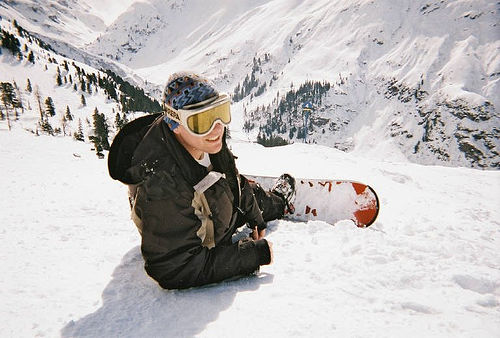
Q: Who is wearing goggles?
A: Snowboarder.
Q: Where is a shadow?
A: On the snow.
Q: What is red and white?
A: Snowboard.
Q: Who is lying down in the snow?
A: A snowboarder.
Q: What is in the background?
A: Trees.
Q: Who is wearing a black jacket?
A: A snowboarder.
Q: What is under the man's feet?
A: A snowboard.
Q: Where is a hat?
A: On man's head.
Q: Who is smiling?
A: The snowboarder.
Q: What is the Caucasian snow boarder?
A: Smiling.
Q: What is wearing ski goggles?
A: The man.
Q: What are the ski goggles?
A: Yellow.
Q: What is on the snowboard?
A: The man.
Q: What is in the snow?
A: Trees.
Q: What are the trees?
A: Pine.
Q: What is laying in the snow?
A: The man.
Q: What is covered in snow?
A: The mountains.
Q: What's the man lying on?
A: Snow.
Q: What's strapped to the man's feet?
A: Snowboard.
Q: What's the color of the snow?
A: White.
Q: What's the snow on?
A: Mountain.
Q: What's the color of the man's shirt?
A: White.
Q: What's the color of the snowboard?
A: Red and white.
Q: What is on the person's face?
A: Snow goggles.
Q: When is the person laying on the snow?
A: Daytime.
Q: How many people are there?
A: One.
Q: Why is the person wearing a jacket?
A: It is cold.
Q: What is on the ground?
A: Snow.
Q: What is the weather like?
A: Cold and sunny.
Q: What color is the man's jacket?
A: Brown.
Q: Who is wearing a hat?
A: The man.